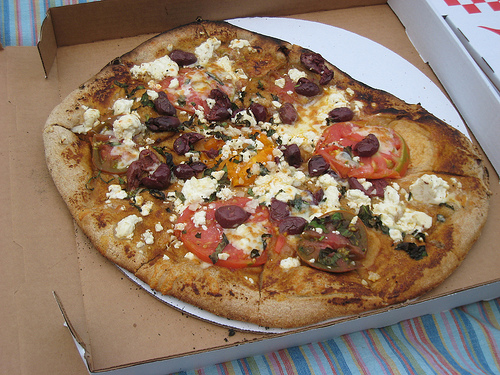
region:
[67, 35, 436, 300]
pizza on white plate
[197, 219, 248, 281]
tomato slice on pizza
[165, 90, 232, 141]
black olives on pizza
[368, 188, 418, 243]
feta cheese on pizza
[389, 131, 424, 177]
green tomato on pizza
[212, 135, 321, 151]
red pepper on pizza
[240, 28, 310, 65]
burnt crust of pizza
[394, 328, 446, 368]
striped cloth box is on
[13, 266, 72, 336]
open cardboard pizza box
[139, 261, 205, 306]
cheese on pizza crust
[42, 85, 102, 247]
part of a crust of pizza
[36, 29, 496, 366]
pizza with toppings in a cardboard box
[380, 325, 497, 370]
white, blue, red and green tablecloth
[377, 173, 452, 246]
cheese topping on a pizza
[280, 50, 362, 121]
olives topping on a pizza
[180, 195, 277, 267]
sliced tomato with olive and cheese on pizza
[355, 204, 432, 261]
cheese and spinach topping on pizza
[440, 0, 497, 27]
white and red checkerboard design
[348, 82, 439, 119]
burned portion of pizza crust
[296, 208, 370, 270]
slice of tomato with spinach on pizza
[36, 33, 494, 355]
a pizza on a cardboard circle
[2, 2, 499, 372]
the pizza is in a cardboard box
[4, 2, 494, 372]
the box is on the table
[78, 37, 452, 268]
feta cheese on pizza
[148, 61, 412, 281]
tomatoes on the pizza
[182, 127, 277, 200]
yellow pepper on the pizza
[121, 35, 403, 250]
olives on the pizza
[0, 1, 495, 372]
cardboard box on the tablecloth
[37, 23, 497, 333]
pizza crust on the cardboard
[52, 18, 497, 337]
cardboard circle is white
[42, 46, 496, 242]
pizza toppings on a pizza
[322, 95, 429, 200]
tomatoes on a pizza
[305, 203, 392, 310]
a green topping on pizza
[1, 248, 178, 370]
cardboard box pizza comes in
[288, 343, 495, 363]
a multi colored table cloth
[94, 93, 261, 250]
some kind of cheese on pizza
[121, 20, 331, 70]
one side of pizza seems burnt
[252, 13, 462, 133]
a white round cardboard insert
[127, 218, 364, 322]
a thick crust on pizza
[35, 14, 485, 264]
a pizza with several toppings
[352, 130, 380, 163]
Bean on top of tomato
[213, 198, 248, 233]
Bean on top of tomato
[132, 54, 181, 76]
Clump of cheese on pizza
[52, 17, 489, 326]
Pizza on cardboard pizza box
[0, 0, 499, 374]
Cardboard pizza box on top of striped tablecloth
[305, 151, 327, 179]
Bean next to cheese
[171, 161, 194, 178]
Bear next to cheese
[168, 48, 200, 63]
Bear next to cheese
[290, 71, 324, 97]
Bear next to cheese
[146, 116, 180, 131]
Bear next to cheese